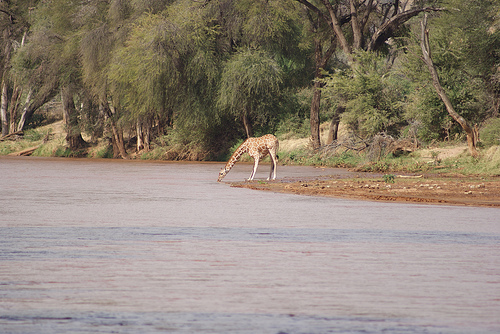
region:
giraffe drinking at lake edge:
[216, 132, 280, 184]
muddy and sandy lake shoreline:
[232, 172, 498, 205]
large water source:
[0, 154, 498, 332]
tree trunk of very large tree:
[325, 0, 418, 93]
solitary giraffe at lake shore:
[0, 133, 498, 331]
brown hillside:
[227, 119, 349, 148]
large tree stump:
[369, 132, 411, 156]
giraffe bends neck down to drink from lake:
[212, 134, 282, 184]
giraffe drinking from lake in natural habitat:
[0, 0, 498, 331]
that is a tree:
[11, 85, 56, 131]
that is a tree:
[0, 63, 15, 130]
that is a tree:
[106, 85, 124, 165]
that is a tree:
[53, 70, 75, 145]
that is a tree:
[341, 25, 363, 81]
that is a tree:
[424, 48, 466, 139]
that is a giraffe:
[213, 122, 291, 185]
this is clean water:
[320, 273, 360, 288]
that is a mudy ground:
[379, 176, 423, 199]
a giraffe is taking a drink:
[16, 14, 475, 262]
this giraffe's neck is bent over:
[203, 123, 301, 199]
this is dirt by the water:
[224, 162, 495, 226]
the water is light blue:
[34, 184, 384, 304]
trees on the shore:
[19, 48, 221, 179]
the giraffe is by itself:
[180, 116, 497, 232]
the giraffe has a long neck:
[184, 132, 252, 194]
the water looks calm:
[16, 169, 259, 321]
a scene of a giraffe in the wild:
[15, 16, 477, 316]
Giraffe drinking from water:
[213, 132, 283, 182]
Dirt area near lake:
[308, 183, 385, 195]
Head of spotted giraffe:
[212, 166, 232, 180]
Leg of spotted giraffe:
[251, 153, 262, 184]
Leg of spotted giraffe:
[270, 150, 280, 180]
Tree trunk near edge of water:
[105, 116, 126, 157]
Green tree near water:
[118, 40, 156, 88]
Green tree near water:
[228, 61, 264, 88]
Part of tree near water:
[251, 8, 298, 41]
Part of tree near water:
[26, 34, 52, 68]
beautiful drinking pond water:
[116, 212, 201, 254]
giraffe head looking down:
[207, 156, 232, 190]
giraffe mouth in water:
[216, 176, 223, 186]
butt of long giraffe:
[265, 127, 280, 149]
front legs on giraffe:
[247, 158, 264, 186]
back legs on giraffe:
[269, 147, 279, 185]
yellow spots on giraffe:
[249, 138, 264, 150]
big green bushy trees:
[123, 31, 270, 124]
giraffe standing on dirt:
[199, 116, 289, 191]